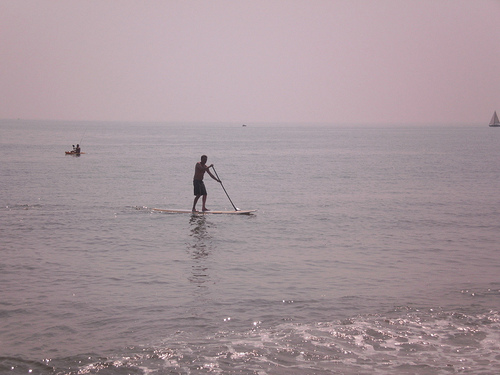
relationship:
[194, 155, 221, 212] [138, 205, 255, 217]
man on surfboard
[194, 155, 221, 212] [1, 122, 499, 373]
man over water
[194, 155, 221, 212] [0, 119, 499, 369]
man in ocean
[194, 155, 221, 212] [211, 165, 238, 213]
man has paddle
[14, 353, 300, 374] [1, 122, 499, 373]
ripple in water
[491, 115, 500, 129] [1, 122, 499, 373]
boat in water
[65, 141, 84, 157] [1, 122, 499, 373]
people in water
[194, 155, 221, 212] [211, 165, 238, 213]
man holding paddle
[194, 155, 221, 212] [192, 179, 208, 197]
man wearing shorts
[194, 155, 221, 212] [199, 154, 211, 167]
man has head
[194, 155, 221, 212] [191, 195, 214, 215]
man has legs